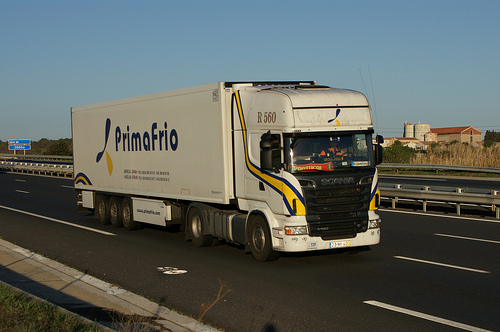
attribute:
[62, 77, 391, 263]
truck — white, long, closed, driving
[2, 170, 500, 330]
road — paved, cement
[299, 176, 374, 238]
grill — black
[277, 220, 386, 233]
lights — off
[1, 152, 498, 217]
fence — metal, protecting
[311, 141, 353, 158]
person — driving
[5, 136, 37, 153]
sign — blue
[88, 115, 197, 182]
logo — blue, yellow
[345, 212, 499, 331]
lines — white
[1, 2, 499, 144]
sky — blue